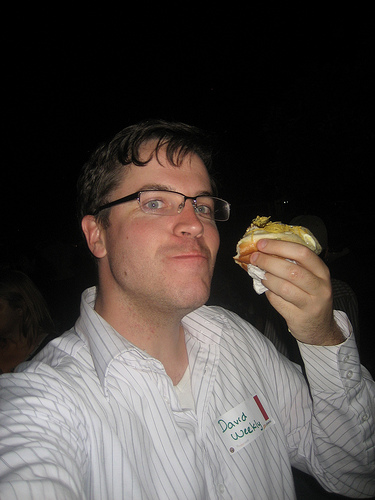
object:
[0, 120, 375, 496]
man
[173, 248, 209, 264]
mouth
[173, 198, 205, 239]
nose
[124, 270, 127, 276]
mole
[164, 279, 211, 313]
chin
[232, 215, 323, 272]
food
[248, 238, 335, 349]
hand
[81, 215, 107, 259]
ear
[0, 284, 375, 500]
shirt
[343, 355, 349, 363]
button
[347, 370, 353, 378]
button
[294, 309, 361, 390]
cuff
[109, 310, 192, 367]
neck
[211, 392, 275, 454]
name tag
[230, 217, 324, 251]
hot dog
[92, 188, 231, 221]
eye glasses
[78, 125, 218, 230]
hair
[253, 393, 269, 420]
line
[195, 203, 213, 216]
eye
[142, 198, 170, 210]
eye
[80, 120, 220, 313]
head